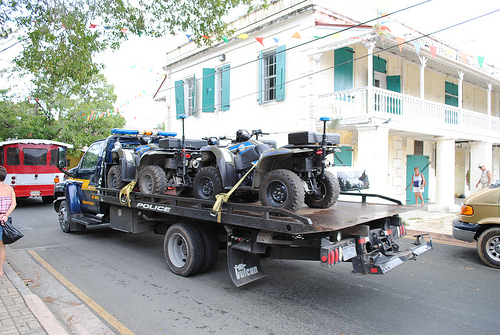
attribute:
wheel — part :
[162, 219, 219, 279]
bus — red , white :
[0, 129, 75, 204]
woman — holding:
[2, 167, 17, 276]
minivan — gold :
[447, 168, 499, 244]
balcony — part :
[319, 86, 498, 141]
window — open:
[252, 44, 299, 106]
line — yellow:
[24, 244, 114, 333]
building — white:
[155, 30, 497, 268]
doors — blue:
[202, 64, 228, 114]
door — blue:
[404, 150, 433, 204]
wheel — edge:
[267, 171, 284, 189]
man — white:
[410, 171, 424, 196]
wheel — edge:
[161, 222, 205, 277]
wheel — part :
[161, 226, 218, 276]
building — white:
[133, 1, 498, 219]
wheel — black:
[150, 205, 207, 270]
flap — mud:
[217, 235, 269, 297]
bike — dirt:
[183, 116, 340, 208]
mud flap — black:
[224, 238, 266, 289]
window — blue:
[264, 54, 277, 100]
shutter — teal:
[202, 69, 213, 111]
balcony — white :
[320, 39, 497, 142]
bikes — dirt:
[148, 126, 305, 189]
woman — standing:
[404, 170, 444, 228]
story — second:
[165, 63, 475, 130]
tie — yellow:
[217, 190, 227, 205]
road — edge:
[203, 305, 396, 331]